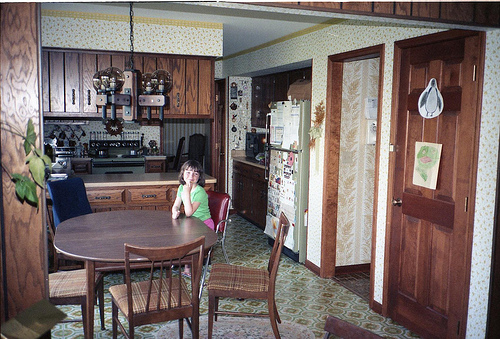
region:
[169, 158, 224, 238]
little girl sitting at kitchen table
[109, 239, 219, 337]
brown wooden chair at table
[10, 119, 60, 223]
green leaves of a plant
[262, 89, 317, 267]
white refrigerator in the kitchen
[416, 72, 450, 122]
drawing of a penguin on a door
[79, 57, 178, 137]
light fixture hanging from ceiling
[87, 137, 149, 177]
silver oven and stove in kitchen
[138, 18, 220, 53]
yellow printed wall paper in kitchen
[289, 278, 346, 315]
yellow linoleum flooring in a kitchen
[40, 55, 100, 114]
dark wood paneled cabinets in kitchen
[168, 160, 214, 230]
Young girl sitting at table in kitchen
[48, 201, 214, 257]
Brown table top in kitchen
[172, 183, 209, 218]
Green top of young girl sitting at table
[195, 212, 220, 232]
Pink shorts of young girl sitting at table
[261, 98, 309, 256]
Green refrigerator in kitchen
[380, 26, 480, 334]
Brown door off kitchen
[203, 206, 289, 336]
Brown cushioned chair at table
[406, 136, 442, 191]
Green drawing attached to door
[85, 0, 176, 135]
Modern design light fixture hanging over table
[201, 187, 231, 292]
Red backed chair at table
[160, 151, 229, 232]
A girl sitting at a table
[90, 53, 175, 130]
A light hanging over a table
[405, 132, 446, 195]
A picture hanging on a door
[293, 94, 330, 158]
A dried grass decoration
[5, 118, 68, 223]
A vine peeping around a corner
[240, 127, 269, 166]
A black microwave on a counter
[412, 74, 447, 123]
A picture of a penguin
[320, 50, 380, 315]
A wooden doorframe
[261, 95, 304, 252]
A heavily decorated refrigerator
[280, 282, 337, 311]
A patterned linoleum floor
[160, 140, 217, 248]
A female sitting at a table.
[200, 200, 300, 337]
A brown wooden chair at a table.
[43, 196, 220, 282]
A brown wooden table top.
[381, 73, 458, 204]
Things hung on a wall.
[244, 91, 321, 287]
A white refrigerator sitting in a kitchen.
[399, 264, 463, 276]
secton of a wooden door.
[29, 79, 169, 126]
section of wooden cabinets.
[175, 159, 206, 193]
A female human head.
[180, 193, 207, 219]
The left arm of a female.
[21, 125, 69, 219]
Green leaves hung on a wall.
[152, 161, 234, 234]
the girl is sited ont he table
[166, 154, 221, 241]
the girl is wearing a green top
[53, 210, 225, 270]
this is a round dining table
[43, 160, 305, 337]
the dining table has five chairs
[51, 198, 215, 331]
the dining table is brown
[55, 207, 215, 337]
the round table is made of wood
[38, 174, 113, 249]
a blue chair on the dining table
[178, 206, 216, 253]
the girl is wearing pink shorts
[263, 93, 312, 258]
this is a white fridge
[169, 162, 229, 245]
the girl is sited on a maroon chair